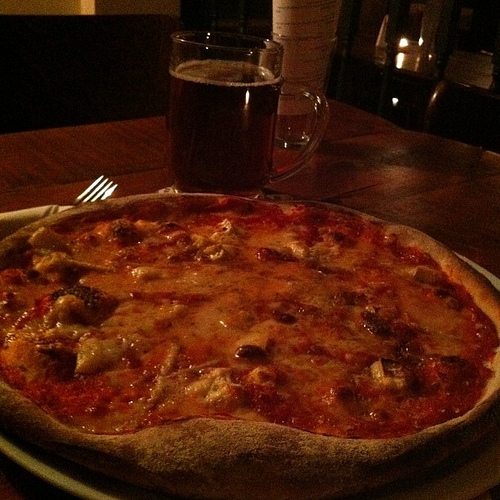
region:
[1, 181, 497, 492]
Pizza on a dish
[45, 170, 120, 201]
Fork on a dish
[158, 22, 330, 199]
Glass of bear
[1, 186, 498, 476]
Pizza with tomato souce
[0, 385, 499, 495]
Brown pizza crust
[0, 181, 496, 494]
Ceramic dish under a pizza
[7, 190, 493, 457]
Pizza with vegetables and tomato sauce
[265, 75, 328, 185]
Handle of glass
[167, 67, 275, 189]
Brown beer in glass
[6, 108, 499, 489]
Pizza on a table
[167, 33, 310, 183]
a mug of beer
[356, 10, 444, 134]
a glass of wine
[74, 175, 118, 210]
the top of a fork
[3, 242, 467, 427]
some type of food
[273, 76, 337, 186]
the handle of a beer mug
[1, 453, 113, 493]
the edge of a plate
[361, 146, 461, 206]
the top of a table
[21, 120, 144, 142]
the edge of a table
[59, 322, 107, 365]
a piece of food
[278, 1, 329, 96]
a bottle of wine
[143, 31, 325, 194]
CUP OF BEER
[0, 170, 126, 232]
SILVER FORK WRAPPED IN NAPKIN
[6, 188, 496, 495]
ROUND CHEESY PIZZA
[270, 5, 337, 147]
MENU IN A GLASS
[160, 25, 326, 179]
GLASS BEER MUG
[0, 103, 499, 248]
WOODEN SQUARE TABLE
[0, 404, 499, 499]
THICK PIZZA CRUST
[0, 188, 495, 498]
PIZZA ON A PLATE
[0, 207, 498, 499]
WHITE PLATE OF PIZZA ON TABLE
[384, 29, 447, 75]
CANDLE LIT ON NEXT TABLE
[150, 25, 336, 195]
beverage in clear glass with handle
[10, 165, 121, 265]
fork laying next to pizza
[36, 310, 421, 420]
pizza toppings in various shapes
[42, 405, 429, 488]
thick crust on side of pizza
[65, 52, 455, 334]
food on top of wooden table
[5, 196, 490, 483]
pizza on top of round metal pan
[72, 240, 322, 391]
melted cheese glistening on pizza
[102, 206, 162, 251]
burnt protrusion on pizza surface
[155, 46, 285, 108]
bubbly foam on top of drink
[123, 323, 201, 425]
long cylindrical ingredient embedded in pizza